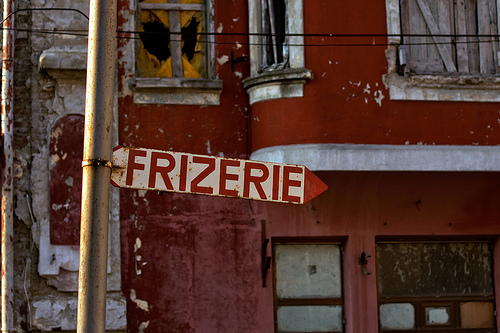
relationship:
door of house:
[261, 232, 358, 332] [13, 9, 489, 326]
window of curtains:
[130, 0, 212, 78] [143, 14, 202, 71]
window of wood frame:
[130, 0, 212, 78] [135, 0, 219, 94]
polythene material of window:
[173, 9, 205, 73] [127, 4, 222, 93]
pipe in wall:
[0, 1, 17, 331] [0, 3, 252, 331]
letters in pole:
[124, 149, 305, 204] [74, 17, 119, 331]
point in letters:
[298, 162, 330, 207] [124, 149, 305, 204]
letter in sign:
[146, 152, 176, 194] [125, 147, 305, 210]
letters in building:
[124, 149, 305, 204] [4, 2, 496, 332]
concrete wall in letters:
[120, 2, 497, 330] [124, 149, 305, 204]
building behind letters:
[4, 2, 496, 332] [124, 149, 305, 204]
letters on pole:
[124, 149, 305, 204] [68, 0, 127, 321]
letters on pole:
[124, 149, 305, 204] [77, 1, 113, 331]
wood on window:
[167, 9, 183, 88] [123, 0, 230, 95]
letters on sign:
[124, 145, 305, 203] [109, 146, 324, 207]